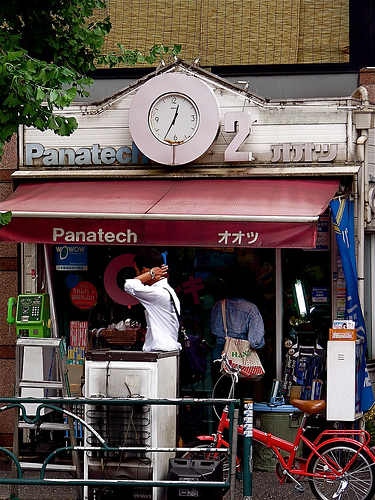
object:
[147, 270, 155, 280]
watch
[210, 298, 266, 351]
jacket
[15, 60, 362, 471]
storefront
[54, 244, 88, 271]
signs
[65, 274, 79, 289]
signs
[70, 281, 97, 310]
signs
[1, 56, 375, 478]
store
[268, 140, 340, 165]
asian writing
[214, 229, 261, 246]
asian writing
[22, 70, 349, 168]
face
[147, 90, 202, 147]
clock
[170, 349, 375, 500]
bicycle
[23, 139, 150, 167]
sign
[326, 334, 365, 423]
mail box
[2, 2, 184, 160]
tree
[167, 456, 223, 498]
tv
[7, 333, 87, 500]
ladder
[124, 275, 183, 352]
shirt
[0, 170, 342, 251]
canopy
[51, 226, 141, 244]
word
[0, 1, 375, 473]
building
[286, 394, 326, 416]
seat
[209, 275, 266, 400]
woman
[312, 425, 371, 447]
rack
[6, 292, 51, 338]
phone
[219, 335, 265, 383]
bag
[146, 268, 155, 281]
wrist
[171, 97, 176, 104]
number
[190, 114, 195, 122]
number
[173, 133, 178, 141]
number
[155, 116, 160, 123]
number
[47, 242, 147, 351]
window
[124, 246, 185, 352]
man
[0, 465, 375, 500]
ground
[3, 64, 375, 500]
business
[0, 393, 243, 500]
rail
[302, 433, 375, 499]
back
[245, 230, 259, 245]
sign